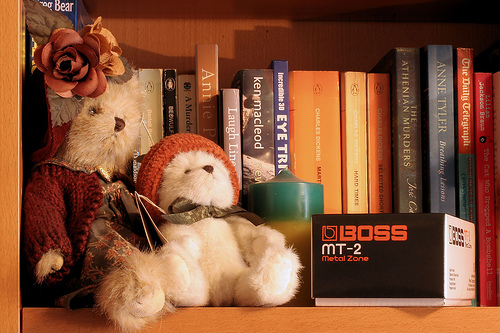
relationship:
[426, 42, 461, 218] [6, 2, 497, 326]
book on shelf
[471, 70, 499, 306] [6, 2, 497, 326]
book on shelf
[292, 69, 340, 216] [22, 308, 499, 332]
book arranged on shelf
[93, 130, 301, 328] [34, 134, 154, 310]
bear wearing a sweater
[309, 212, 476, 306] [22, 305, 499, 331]
box on shelf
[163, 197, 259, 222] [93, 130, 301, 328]
bow on bear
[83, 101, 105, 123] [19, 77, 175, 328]
eye of bear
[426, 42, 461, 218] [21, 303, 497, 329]
book on shelf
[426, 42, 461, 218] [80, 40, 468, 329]
book on shelf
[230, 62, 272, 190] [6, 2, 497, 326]
book on shelf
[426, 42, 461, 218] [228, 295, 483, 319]
book on shelf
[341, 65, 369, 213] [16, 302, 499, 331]
book on shelf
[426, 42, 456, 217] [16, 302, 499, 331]
book on shelf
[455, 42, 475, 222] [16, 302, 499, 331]
book on shelf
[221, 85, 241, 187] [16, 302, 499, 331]
book on shelf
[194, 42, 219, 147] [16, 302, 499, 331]
book on shelf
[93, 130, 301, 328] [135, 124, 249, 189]
bear wears hat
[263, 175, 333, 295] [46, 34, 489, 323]
candle on shelf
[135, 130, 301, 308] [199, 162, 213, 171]
bear has nose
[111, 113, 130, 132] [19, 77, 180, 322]
nose is on bear